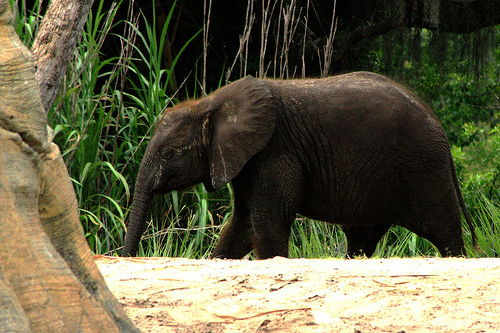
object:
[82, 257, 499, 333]
ground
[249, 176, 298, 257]
leg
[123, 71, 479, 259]
elephant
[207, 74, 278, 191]
ear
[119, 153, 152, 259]
trunk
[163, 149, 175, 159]
eye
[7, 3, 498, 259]
grass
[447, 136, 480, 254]
tail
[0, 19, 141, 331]
stump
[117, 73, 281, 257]
head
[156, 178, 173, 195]
mouth